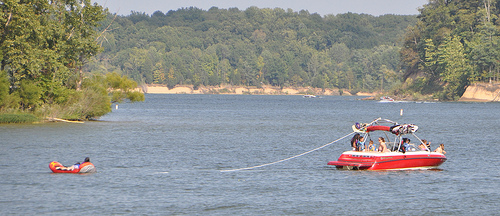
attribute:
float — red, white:
[47, 159, 94, 175]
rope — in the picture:
[217, 117, 383, 180]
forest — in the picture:
[1, 0, 498, 128]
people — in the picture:
[350, 119, 445, 154]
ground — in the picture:
[412, 122, 452, 169]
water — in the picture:
[217, 102, 293, 131]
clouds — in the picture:
[186, 2, 442, 52]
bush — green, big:
[46, 59, 142, 121]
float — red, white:
[295, 87, 453, 174]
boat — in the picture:
[325, 96, 471, 198]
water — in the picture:
[196, 115, 263, 123]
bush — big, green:
[67, 68, 147, 123]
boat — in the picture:
[322, 150, 469, 195]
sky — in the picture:
[310, 2, 422, 13]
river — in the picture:
[166, 96, 273, 133]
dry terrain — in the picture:
[80, 85, 383, 96]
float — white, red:
[334, 137, 460, 186]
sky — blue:
[92, 1, 446, 19]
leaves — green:
[25, 30, 73, 86]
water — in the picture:
[338, 187, 404, 200]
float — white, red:
[32, 143, 97, 208]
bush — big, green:
[446, 62, 476, 94]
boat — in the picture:
[330, 116, 448, 170]